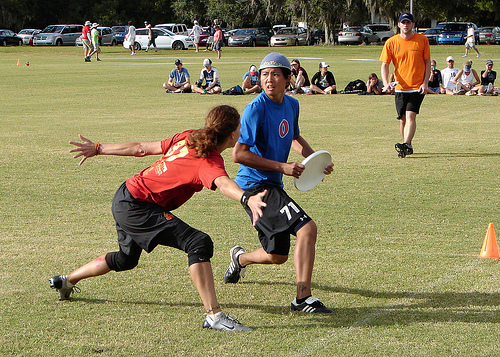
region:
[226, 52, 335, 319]
Young man playing frisbee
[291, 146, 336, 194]
White frisbee in hands of young man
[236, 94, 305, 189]
Blue shirt on male frisbee player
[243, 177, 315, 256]
Black shorts on male frisbee player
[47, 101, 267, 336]
Young woman attempting to block frisbee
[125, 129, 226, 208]
Red shirt on female frisbee player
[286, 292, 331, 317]
Black and white shoe on male frisbee player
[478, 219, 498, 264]
Orange cone on frisbee field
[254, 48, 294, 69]
Blue hat on male frisbee player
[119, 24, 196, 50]
White car parked near frisbee field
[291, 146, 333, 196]
man holding white Frisbee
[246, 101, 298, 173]
man wearing blue and red shirt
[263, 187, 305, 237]
man wearing black and white shorts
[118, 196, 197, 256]
young woman wearing black shorts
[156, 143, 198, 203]
young woman wearing red and white shirt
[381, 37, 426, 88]
man wearing orange shirt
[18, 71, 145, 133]
green and brown grass on field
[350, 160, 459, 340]
green and brown grass on field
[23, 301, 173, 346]
green and brown grass on field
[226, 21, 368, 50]
cars parked in parking lot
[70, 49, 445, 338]
people playing a game with a Frisbee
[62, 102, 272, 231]
person with their hands stretched out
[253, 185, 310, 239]
number on player's shorts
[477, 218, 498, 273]
orange cone on grass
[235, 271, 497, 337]
shadows on grass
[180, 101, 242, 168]
person with their hair pulled into a ponytail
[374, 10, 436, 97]
man wearing an orange shirt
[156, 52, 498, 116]
people sitting on the grass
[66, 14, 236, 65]
people walking in the distance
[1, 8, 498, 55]
parked cars in the distance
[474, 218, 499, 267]
Orange cone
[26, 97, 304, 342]
Frisbee player blocking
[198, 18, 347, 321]
Boy about to throw a frisbee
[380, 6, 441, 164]
Guy in orange shirt walking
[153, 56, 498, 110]
Spectators of sport sitting in grass field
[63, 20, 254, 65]
People walking in the distance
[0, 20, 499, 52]
Cars parked in the distance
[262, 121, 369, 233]
White frisbe in boy's hands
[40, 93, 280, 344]
Frisbee player wearing red shirt and black shorts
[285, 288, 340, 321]
Adidas brand black shoe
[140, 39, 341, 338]
two people playing frisbee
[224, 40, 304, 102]
man wearing blue hat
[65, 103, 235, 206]
man wearing red shirt with yellow letters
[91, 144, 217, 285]
man wearing black shorts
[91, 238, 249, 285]
man wearing black knee pads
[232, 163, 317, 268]
man wearing black shorts with white numbers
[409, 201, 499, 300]
orange cone in field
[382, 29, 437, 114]
man wearing orange shirt and black shorts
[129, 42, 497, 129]
spectators watching frisbee game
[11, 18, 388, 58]
many cars parked in background